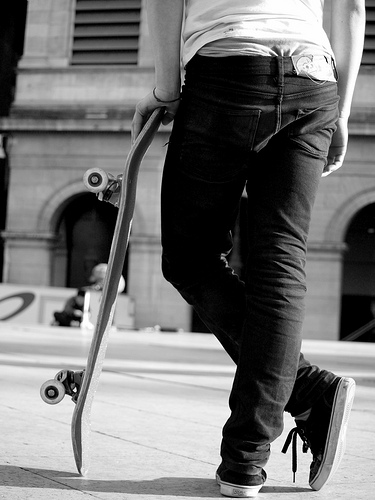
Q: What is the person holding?
A: Skateboard.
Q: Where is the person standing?
A: Street.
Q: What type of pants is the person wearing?
A: Jeans.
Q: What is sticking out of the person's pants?
A: Underwear.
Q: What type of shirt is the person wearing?
A: T-shirt.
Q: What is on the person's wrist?
A: String.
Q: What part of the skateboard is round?
A: Wheels.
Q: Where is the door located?
A: Building.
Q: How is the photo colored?
A: Black and white.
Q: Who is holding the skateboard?
A: The person.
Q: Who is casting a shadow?
A: The person.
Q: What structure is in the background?
A: The building.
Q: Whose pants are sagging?
A: The person's.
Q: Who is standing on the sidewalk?
A: The person.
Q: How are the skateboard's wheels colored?
A: White.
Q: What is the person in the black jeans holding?
A: Skateboard.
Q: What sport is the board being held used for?
A: Skateboarding.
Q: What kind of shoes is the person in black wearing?
A: Sneakers.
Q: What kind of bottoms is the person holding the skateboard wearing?
A: Jeans.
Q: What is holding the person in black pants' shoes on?
A: Laces.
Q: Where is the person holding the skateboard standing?
A: Sidewalk.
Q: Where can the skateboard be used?
A: Skatepark.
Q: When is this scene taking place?
A: Daytime.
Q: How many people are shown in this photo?
A: One.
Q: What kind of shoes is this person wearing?
A: Sneakers.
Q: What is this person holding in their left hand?
A: Skateboard.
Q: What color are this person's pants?
A: Black.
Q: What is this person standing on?
A: Concrete.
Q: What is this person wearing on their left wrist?
A: Bracelet.